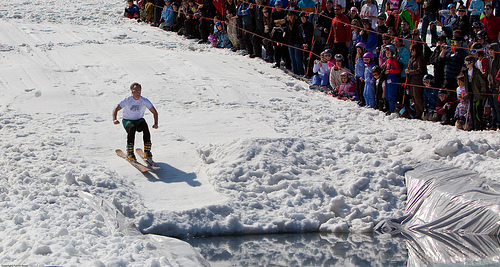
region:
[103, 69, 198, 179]
A man on skis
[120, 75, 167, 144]
A man wearing a white shirt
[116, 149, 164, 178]
Two skis on snow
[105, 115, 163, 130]
The hands of a man skiing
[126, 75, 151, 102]
The head of a man skiing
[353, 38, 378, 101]
Two people wearing purple helmets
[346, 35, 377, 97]
Two people wearing blue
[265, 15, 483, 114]
A large crowd of people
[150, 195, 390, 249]
Snow at the edge of water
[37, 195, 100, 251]
Snow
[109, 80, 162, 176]
a man skiing on snow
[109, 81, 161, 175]
a man wearing a white shirt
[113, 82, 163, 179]
a man wearing sunglasses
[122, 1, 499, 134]
a crowd standing behind a roped off area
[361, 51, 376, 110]
a person wearing a purple helmet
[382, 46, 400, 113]
a person wearing a red shirt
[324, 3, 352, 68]
a man wearing a red jacket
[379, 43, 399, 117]
a person wearing blue pants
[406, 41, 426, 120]
a person wearing brown clothes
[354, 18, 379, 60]
a person wearing a blue jacket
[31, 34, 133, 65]
lines in the white snow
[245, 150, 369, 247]
deep holes in the snow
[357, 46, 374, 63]
pink helmet on person's head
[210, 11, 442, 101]
orange lines on track side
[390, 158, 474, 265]
large selection of shiny silver plastic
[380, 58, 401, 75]
long sleeve red sweater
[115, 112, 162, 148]
green ski pants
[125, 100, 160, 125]
logo on white tee shirt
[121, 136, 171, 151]
orange lines on socks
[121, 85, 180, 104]
man wearing shiny goggles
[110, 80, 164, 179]
the man is on skis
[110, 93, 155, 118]
the man is wearing a white shirt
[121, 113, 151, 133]
the man is wearing green shorts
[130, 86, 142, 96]
the man is wearing goggles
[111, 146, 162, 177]
the skis are yellow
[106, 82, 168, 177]
the skier is approaching water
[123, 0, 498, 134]
an audience watches the skier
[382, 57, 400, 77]
one child is wearing a red shirt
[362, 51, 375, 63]
a child is wearing a purple helmet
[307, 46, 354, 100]
one group of people is sitting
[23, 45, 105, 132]
the snow is white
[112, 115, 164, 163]
the pants are black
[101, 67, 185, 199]
the man is skiing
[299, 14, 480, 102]
the people are watching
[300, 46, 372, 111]
the children are sitting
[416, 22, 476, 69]
the people are standing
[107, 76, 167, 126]
the shirt is white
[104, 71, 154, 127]
the man has a helmet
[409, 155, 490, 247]
the tarp is white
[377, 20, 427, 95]
the rope is red